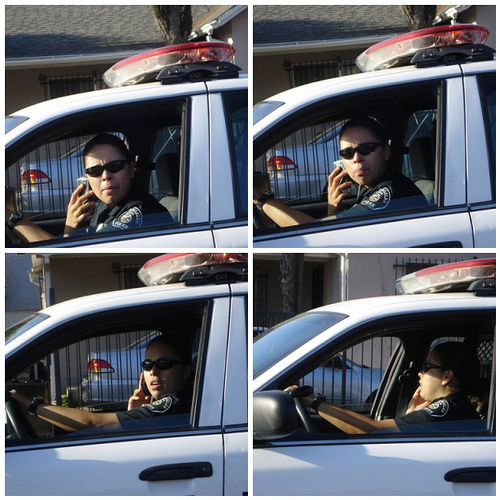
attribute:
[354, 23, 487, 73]
lighs — red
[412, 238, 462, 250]
handle — black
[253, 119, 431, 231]
man — driving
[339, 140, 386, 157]
sunglasses — black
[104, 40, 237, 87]
light — red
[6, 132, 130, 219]
gate — black